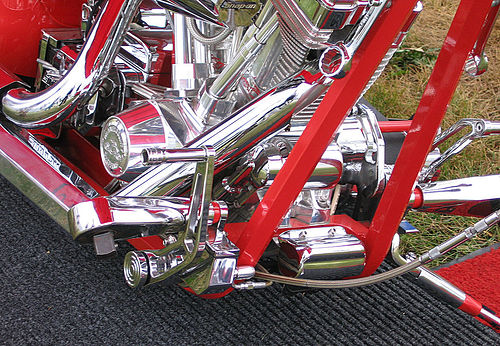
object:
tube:
[104, 63, 337, 200]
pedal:
[124, 148, 239, 295]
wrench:
[317, 0, 389, 80]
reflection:
[59, 51, 343, 148]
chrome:
[0, 2, 500, 334]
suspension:
[132, 0, 394, 200]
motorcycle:
[2, 2, 500, 330]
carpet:
[0, 164, 500, 346]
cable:
[258, 212, 500, 290]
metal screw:
[123, 251, 148, 291]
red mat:
[433, 247, 500, 326]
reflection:
[3, 79, 87, 128]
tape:
[455, 296, 484, 316]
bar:
[204, 11, 500, 290]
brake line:
[255, 209, 498, 291]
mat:
[0, 178, 497, 346]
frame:
[238, 0, 500, 332]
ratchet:
[69, 197, 229, 258]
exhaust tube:
[0, 0, 141, 130]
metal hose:
[185, 10, 237, 45]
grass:
[359, 0, 500, 269]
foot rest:
[408, 171, 498, 221]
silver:
[342, 48, 352, 62]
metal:
[319, 43, 350, 78]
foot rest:
[66, 149, 234, 301]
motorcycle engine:
[90, 0, 423, 301]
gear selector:
[419, 117, 499, 183]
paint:
[2, 0, 498, 297]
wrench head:
[319, 46, 351, 80]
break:
[140, 146, 216, 276]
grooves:
[24, 249, 45, 333]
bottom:
[253, 198, 500, 334]